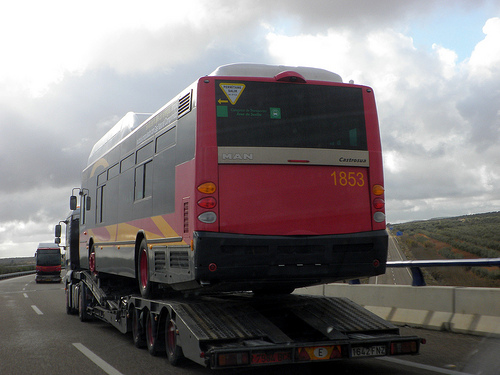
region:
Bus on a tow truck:
[57, 60, 431, 371]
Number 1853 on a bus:
[328, 164, 368, 193]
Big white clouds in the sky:
[1, 2, 498, 259]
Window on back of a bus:
[212, 75, 372, 157]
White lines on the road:
[20, 267, 125, 372]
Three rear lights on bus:
[193, 174, 221, 229]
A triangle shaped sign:
[215, 75, 249, 110]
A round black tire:
[130, 237, 157, 298]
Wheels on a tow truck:
[59, 275, 191, 367]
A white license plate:
[343, 338, 390, 361]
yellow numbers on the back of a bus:
[325, 171, 368, 190]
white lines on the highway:
[18, 276, 75, 374]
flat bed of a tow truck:
[53, 129, 433, 368]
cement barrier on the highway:
[396, 220, 497, 371]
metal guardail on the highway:
[394, 249, 498, 292]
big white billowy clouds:
[384, 38, 487, 198]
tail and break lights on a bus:
[198, 158, 221, 234]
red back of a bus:
[218, 167, 329, 234]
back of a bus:
[30, 232, 65, 299]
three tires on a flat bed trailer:
[114, 291, 199, 366]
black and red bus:
[60, 58, 395, 293]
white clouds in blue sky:
[13, 15, 49, 60]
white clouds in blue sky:
[26, 107, 60, 163]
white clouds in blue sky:
[9, 153, 34, 220]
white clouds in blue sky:
[26, 43, 81, 119]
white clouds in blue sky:
[80, 5, 116, 55]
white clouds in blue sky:
[159, 11, 233, 51]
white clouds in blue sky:
[281, 15, 338, 48]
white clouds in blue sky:
[400, 10, 475, 82]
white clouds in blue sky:
[409, 126, 468, 194]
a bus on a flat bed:
[70, 64, 387, 291]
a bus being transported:
[67, 64, 389, 296]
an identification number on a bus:
[327, 168, 369, 190]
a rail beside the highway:
[384, 257, 498, 269]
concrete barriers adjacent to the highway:
[292, 284, 497, 339]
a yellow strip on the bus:
[148, 214, 179, 241]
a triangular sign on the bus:
[219, 80, 246, 105]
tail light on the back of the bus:
[198, 196, 217, 211]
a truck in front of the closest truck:
[33, 243, 60, 282]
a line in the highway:
[72, 342, 122, 372]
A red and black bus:
[46, 52, 393, 282]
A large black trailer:
[56, 270, 403, 360]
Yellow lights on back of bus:
[190, 180, 222, 193]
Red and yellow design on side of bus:
[96, 220, 190, 250]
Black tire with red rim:
[131, 243, 154, 295]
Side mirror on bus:
[58, 180, 90, 225]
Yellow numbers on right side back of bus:
[317, 156, 374, 195]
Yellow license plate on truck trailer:
[294, 343, 360, 373]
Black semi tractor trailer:
[50, 196, 94, 311]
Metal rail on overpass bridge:
[393, 248, 498, 326]